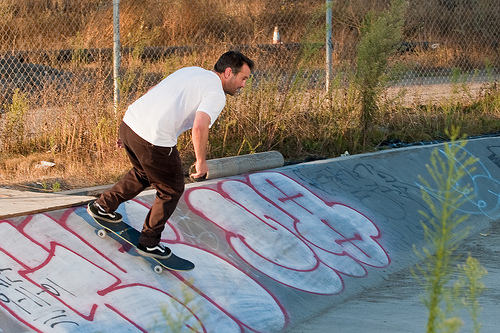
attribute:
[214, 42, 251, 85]
hair — dark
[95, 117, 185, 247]
pants — brown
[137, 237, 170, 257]
shoe — black, white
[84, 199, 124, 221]
shoe — black, white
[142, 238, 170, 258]
shoe — white, black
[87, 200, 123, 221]
shoe — white, black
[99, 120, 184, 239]
pants — brown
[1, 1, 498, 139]
fence — chain link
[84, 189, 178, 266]
shoes — black, white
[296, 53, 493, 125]
shrubs — green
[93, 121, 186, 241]
pants — brown